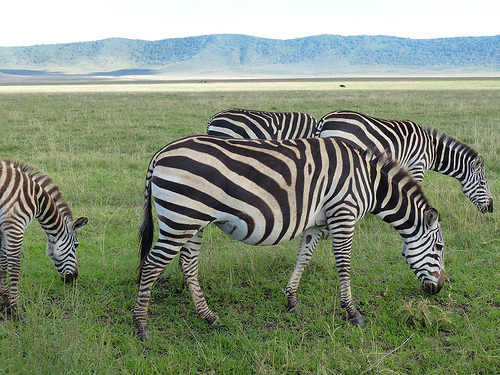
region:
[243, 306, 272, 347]
part of a ground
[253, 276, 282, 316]
part of a ground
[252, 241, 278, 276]
part of a ground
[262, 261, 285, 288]
part of a ground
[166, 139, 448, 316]
this is a zebra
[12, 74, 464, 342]
the zebras are four in number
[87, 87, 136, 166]
this is a grass area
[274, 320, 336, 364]
the grass is green in color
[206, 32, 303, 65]
this is a mountain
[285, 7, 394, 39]
this is the sky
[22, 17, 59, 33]
the sky is blue in color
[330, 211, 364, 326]
this is the leg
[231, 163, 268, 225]
the zebra has white and black strips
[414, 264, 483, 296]
the zebra is feeding on the grass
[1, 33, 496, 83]
Hills in the background.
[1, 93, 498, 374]
Green grass covering the ground.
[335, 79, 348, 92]
Animal in the background.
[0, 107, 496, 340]
Zebras in the grass.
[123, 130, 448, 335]
Zebra eating the grass.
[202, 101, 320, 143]
black and white stripes on the zebra.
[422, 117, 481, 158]
Black and white mane on the zebra.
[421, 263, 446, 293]
Brown nose on zebra.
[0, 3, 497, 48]
white sky in the background.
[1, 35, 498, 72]
Trees covering the hills.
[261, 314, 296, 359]
part of a grass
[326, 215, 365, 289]
aprt of a leg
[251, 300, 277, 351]
partg of a grpimd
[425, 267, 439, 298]
part of a mouth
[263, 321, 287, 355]
part of a ground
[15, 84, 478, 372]
four zebras on the field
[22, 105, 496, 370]
the zebras are standing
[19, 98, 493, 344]
the zebras are grazing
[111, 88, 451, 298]
the zebras are stripped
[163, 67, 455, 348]
they are black and white in colour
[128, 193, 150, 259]
they tails are black in colour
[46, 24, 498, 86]
the mountain is large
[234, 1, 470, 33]
the sky is white in colour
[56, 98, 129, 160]
the grass is green in colour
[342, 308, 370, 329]
the hooves are black in colour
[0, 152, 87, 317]
The front end of a zebra with no back end visible.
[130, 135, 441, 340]
The largest black and white fully visible zebra.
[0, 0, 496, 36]
Thin white sky.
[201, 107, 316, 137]
Black and white zebra with no visible head.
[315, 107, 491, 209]
Black and white zebra with no legs visible and a black right eye.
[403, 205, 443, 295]
Head of the largest black and white zebra.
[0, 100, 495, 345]
the zebras heads down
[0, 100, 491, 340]
stripes on zebras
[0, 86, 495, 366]
the grassy green field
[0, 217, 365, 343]
the legs of zebras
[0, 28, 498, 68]
the hills in back